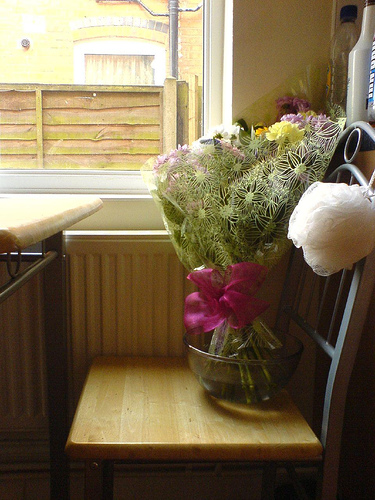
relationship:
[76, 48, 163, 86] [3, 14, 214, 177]
window on building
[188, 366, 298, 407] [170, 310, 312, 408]
water in bowl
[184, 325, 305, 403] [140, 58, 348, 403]
glass bowl has bouquet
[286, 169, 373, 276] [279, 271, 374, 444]
shower poof on back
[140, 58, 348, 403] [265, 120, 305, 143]
bouquet has flower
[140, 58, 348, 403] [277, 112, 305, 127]
bouquet has flower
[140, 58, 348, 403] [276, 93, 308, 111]
bouquet has flower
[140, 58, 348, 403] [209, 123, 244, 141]
bouquet has flower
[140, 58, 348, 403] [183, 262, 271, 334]
bouquet has bow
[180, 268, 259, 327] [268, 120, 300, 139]
bow on flower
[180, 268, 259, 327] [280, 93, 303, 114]
bow on flower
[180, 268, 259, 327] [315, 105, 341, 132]
bow on flower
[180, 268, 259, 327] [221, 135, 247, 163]
bow on flower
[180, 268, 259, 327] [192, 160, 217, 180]
bow on flower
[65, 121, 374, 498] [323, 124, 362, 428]
chair with back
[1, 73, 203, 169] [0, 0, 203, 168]
wall through window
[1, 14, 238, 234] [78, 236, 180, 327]
window in wall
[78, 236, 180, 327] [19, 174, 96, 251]
wall in front table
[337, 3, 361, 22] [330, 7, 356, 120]
cap on bottle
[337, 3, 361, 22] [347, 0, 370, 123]
cap on bottle